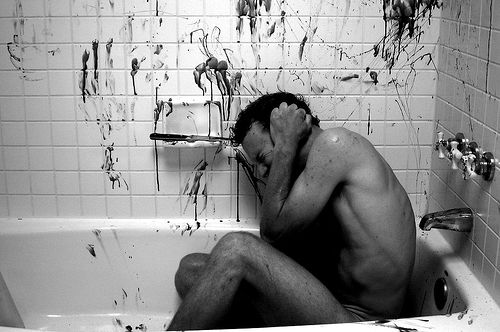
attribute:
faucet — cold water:
[438, 131, 497, 191]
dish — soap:
[157, 97, 224, 147]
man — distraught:
[164, 90, 427, 319]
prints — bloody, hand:
[73, 35, 145, 155]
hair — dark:
[221, 89, 315, 149]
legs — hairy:
[164, 231, 351, 330]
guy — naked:
[163, 93, 417, 329]